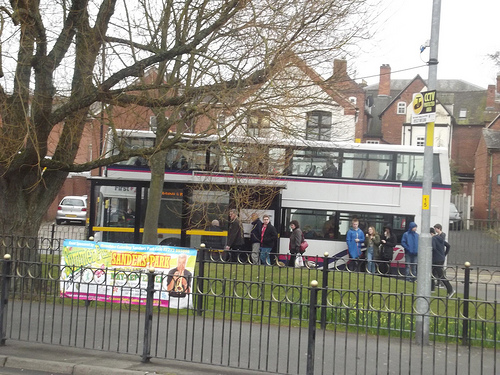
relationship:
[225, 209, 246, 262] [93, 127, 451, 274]
man next to bus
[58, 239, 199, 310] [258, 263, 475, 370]
banner on fence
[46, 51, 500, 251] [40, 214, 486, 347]
building on road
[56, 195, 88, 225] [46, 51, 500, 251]
car near building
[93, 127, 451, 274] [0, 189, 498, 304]
bus on road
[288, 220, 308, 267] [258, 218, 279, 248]
person wearing black coat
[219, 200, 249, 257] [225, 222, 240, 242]
man wearing jacket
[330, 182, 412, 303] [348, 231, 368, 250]
boy wearing jacket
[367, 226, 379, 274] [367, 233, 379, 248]
girl wearing jacket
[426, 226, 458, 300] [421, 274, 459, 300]
man wearing shoes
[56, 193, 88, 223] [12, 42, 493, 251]
car parked by building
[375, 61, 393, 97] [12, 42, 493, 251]
chimney atop a building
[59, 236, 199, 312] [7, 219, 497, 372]
banner hanging on fence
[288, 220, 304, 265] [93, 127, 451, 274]
person waiting for bus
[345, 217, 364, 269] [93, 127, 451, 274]
person waiting for bus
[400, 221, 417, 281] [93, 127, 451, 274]
person waiting for bus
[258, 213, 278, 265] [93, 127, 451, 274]
person waiting for bus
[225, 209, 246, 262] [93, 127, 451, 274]
man waiting for bus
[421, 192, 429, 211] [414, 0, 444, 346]
sticker on lamp post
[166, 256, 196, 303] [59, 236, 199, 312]
man on banner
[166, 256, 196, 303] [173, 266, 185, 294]
man playing trumpet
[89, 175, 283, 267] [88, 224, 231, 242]
bus stop with stripe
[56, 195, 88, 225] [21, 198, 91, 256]
car parked in driveway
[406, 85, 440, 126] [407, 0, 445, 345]
sign hanging on lamp post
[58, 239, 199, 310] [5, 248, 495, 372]
banner on fence